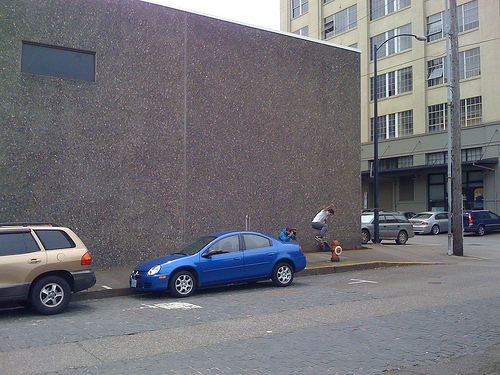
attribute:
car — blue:
[128, 224, 308, 300]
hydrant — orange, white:
[330, 238, 342, 262]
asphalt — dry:
[355, 276, 432, 295]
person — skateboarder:
[307, 204, 339, 245]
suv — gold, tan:
[1, 210, 96, 323]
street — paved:
[334, 268, 438, 299]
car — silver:
[409, 206, 450, 234]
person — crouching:
[281, 222, 297, 241]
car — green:
[360, 209, 414, 245]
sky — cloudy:
[201, 0, 290, 25]